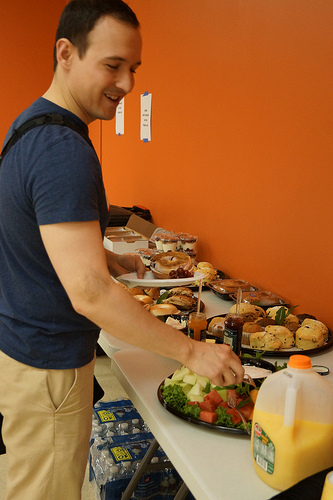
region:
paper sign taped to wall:
[138, 86, 152, 143]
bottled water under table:
[79, 393, 166, 498]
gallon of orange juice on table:
[248, 347, 331, 495]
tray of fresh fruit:
[151, 349, 288, 439]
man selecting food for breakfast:
[3, 0, 246, 498]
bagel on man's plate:
[148, 249, 191, 278]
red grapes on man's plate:
[167, 266, 192, 279]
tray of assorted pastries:
[196, 298, 331, 355]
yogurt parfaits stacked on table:
[148, 226, 200, 258]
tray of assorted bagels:
[122, 283, 206, 329]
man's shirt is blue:
[14, 86, 119, 374]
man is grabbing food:
[0, 5, 313, 418]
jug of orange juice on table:
[235, 338, 331, 480]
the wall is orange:
[2, 2, 324, 318]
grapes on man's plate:
[156, 254, 204, 291]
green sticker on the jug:
[241, 414, 296, 492]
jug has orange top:
[289, 349, 310, 374]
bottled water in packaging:
[76, 386, 155, 491]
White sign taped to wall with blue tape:
[139, 87, 158, 147]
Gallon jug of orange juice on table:
[254, 355, 332, 485]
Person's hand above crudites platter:
[181, 344, 276, 428]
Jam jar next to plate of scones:
[223, 292, 324, 358]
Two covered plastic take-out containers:
[209, 265, 280, 306]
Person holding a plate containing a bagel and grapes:
[123, 245, 204, 288]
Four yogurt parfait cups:
[153, 226, 198, 255]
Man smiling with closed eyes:
[13, 6, 152, 118]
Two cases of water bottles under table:
[95, 397, 174, 497]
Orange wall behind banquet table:
[139, 136, 332, 333]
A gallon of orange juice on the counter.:
[242, 358, 324, 472]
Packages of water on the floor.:
[93, 403, 139, 492]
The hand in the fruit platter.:
[196, 333, 248, 407]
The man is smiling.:
[85, 76, 145, 120]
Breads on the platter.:
[246, 309, 307, 342]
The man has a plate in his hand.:
[115, 243, 203, 290]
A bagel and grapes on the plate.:
[145, 238, 195, 278]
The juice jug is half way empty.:
[254, 372, 331, 449]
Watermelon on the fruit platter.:
[199, 390, 246, 428]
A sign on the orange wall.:
[135, 90, 169, 158]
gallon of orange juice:
[247, 360, 332, 497]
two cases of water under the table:
[100, 405, 139, 497]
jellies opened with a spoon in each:
[187, 301, 252, 348]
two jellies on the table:
[195, 291, 256, 353]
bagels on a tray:
[132, 284, 199, 316]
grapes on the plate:
[162, 260, 194, 283]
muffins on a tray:
[244, 316, 299, 336]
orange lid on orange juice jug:
[279, 352, 315, 380]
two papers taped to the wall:
[106, 92, 174, 150]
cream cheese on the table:
[159, 313, 187, 332]